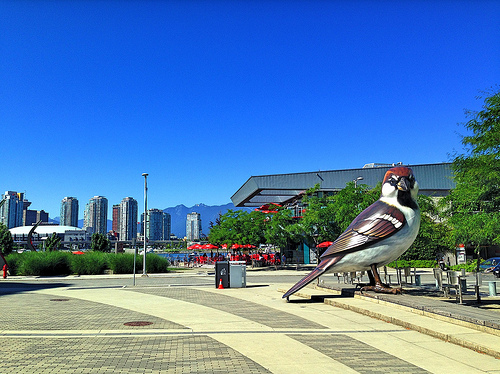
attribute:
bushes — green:
[9, 250, 168, 269]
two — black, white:
[216, 259, 250, 288]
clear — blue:
[1, 1, 500, 225]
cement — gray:
[0, 277, 499, 372]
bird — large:
[289, 145, 416, 322]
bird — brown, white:
[279, 140, 418, 319]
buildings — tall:
[6, 168, 193, 256]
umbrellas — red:
[181, 230, 268, 251]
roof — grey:
[217, 157, 482, 188]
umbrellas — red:
[177, 228, 267, 255]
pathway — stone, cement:
[9, 245, 482, 363]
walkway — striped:
[1, 257, 496, 371]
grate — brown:
[124, 317, 155, 330]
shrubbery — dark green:
[0, 249, 170, 278]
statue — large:
[282, 164, 422, 297]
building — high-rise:
[62, 196, 78, 229]